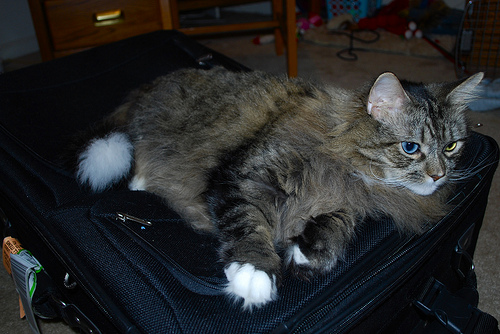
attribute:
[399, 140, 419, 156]
eye — blue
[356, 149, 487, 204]
whiskers — white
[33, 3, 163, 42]
drawer — wooden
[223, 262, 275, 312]
paw — cat's paw, fluffy, white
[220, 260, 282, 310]
paw — white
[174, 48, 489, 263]
cat — yellow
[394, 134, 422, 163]
eye — blue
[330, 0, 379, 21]
crate — blue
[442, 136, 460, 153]
eye —  yellow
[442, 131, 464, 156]
eye — yellow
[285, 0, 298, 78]
leg — wooden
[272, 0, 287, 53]
leg — wooden